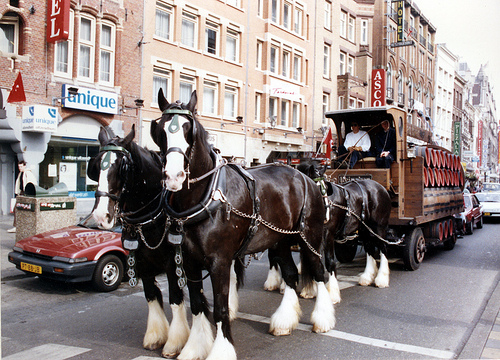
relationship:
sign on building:
[387, 0, 418, 49] [373, 0, 438, 143]